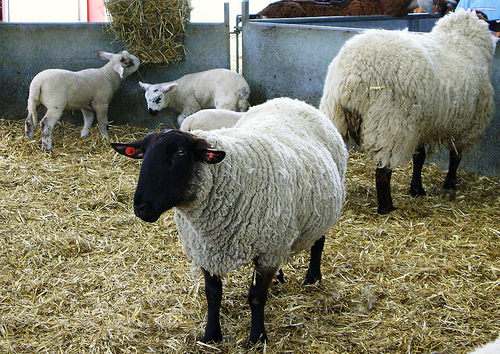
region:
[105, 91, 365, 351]
A white and black sheep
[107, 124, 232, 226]
A black sheep's head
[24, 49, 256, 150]
Two lambs in a stall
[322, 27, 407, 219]
The backside of a sheep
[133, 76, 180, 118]
The head of a lamb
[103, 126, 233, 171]
Tagged ears of a sheep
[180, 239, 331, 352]
A sheep's legs standing in hay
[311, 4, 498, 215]
A thick coated sheep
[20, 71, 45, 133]
A lamb's tail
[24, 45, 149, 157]
A lamb chewing hay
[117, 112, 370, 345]
A lamb in the hay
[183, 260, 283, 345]
The front legs of the lamb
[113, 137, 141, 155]
A tag on the lamb's ear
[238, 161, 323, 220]
White fur on the lamb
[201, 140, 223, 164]
The left ear of the lamb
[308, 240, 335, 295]
The left back leg of the lamb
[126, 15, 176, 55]
A bale of hay by the small lambs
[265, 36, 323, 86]
A dirty white wall by the lambs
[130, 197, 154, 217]
The nose of the lamb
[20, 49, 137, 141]
A small lamb eating hay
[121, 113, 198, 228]
white sheep with black face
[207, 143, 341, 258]
sheep has white fleece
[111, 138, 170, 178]
red marker on sheep's ear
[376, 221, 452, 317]
straw on floor of sheep's pen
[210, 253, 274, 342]
sheep has black legs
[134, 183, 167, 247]
sheep has black nose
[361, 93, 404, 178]
sheep has fleece hanging down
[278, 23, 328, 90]
gray dirty walls of sheep's pen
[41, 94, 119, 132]
sheep with no wool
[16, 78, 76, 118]
short stubby sheep tail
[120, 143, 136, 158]
Tag in sheep's right ear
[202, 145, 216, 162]
Tag in sheep's left ear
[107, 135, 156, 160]
Right ear of sheep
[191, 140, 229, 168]
Left ear of sheep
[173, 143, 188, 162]
Left eye of sheep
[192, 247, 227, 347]
Front right leg of sheep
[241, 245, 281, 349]
Front left leg of sheep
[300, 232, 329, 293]
Back left leg of sheep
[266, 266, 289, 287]
Back right leg of sheep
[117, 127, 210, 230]
Head of the sheep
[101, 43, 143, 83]
Head of a sheep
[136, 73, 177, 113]
Head of a sheep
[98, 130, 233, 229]
Head of a sheep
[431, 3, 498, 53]
Head of a sheep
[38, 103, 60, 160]
Leg of a sheep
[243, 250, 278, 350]
Leg of a sheep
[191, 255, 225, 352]
Leg of a sheep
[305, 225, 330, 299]
Leg of a sheep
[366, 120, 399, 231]
Leg of a sheep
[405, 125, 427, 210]
Leg of a sheep